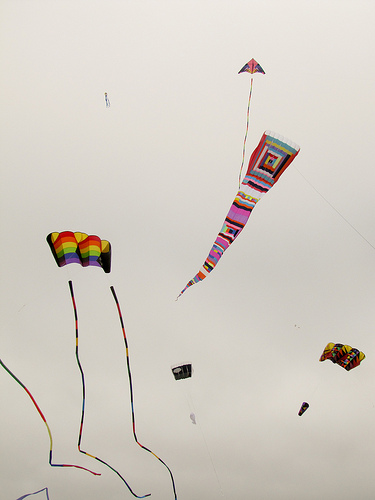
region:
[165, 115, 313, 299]
bright pink and multicolored kite with a long conical tail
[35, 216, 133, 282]
square rainbow colored kite with two tails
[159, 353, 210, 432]
square black and white kite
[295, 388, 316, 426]
small black wind sock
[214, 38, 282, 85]
triangular orange and blue kite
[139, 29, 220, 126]
grey cloud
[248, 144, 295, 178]
spiral of multicolored fabric that changes color on each line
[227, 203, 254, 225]
pink, purple, and black stripe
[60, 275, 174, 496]
two multicolored streaming tails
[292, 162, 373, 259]
white string connected to a kite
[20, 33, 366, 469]
colorful kites in air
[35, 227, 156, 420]
rainbow kite on left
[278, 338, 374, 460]
small psychedelic kite on right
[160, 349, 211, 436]
white and black kite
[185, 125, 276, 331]
tribal pattern kite with long tail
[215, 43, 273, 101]
triangle pink kite in air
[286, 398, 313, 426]
kite with lantern at bottom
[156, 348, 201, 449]
kite with white lantern floating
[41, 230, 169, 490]
kite with very long tails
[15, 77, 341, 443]
beautiful kites floating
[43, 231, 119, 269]
kite is rainbow striped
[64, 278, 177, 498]
kite has two tails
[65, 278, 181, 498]
tails are rainbow striped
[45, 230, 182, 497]
kite is flying in sky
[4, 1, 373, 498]
sky is overcast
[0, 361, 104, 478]
another kite's tail is next to the kite tail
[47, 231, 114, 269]
kite is rectangular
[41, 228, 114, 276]
kite is wavy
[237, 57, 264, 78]
kite is triangle shaped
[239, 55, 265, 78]
kite is pink and blue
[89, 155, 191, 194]
gray clouds in the sky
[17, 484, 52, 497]
blue ribbon in the sky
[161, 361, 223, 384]
small black and white kite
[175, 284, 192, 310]
edge of rainbow kite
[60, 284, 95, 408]
large string on kite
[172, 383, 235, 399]
thin string on the kite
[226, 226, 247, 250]
pink and green colors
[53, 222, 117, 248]
yellow color at edge of kite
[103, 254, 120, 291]
black at the edge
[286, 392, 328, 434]
cone shaped tail on kite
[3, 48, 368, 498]
Several kites are flying.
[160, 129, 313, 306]
The kite is very colorful.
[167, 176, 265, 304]
The kite has a long tail.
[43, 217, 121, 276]
The kite is striped.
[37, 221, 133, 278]
The kite's stripes are the rainbow.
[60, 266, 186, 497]
The kite has long tails.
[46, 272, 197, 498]
The tails are skinny.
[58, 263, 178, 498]
The tails are multi-colored.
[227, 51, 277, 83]
The kite is triangular shaped.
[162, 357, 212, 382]
The kite is black.